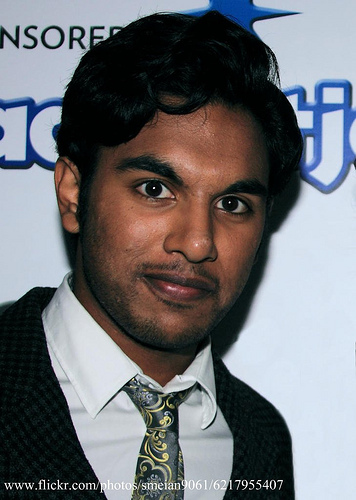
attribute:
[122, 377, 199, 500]
tie — yellow, grey, patterned, black, paisley, gold, silver, gray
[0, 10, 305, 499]
man — not smiling, indian, looking ahead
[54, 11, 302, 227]
hair — black, dark, short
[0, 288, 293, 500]
suit — dressy, houndstooth, dark, sporty, checkered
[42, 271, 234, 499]
shirt — white, dressy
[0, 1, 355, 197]
advertisement — blue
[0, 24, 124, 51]
letters — black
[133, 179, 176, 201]
eye — dark, large, brown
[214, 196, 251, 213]
eye — dark, large, brown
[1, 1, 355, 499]
billboard — white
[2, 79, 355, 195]
word — blue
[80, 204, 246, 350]
whiskers — dark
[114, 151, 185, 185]
eyebrow — black, bushy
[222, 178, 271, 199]
eyebrow — black, bushy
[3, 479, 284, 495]
website — white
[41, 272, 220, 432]
collar — white